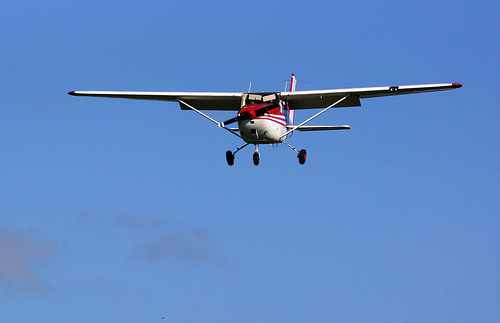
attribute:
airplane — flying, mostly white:
[2, 3, 499, 323]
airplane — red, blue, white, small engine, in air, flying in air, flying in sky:
[67, 73, 468, 166]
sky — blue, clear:
[3, 3, 499, 319]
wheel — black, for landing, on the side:
[224, 149, 237, 167]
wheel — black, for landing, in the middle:
[253, 151, 263, 168]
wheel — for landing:
[299, 147, 307, 165]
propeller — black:
[216, 103, 281, 133]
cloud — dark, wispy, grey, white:
[4, 203, 215, 322]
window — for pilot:
[246, 94, 262, 103]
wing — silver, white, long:
[284, 81, 464, 109]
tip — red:
[451, 79, 463, 92]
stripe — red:
[252, 115, 290, 128]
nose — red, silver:
[235, 103, 274, 139]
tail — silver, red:
[285, 73, 298, 129]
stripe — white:
[222, 119, 227, 126]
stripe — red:
[286, 76, 296, 118]